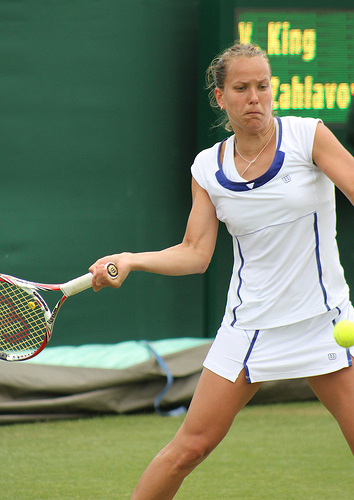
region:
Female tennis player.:
[128, 55, 347, 496]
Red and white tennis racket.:
[3, 216, 88, 368]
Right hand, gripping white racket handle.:
[61, 252, 126, 304]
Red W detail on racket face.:
[1, 284, 28, 354]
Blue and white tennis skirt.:
[213, 316, 352, 384]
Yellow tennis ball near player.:
[334, 316, 352, 356]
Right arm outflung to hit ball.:
[101, 164, 226, 301]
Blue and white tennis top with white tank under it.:
[197, 131, 342, 318]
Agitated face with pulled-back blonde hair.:
[207, 37, 283, 140]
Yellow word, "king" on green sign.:
[267, 22, 323, 72]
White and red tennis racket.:
[0, 258, 119, 358]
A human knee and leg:
[121, 380, 261, 493]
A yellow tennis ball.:
[332, 320, 349, 343]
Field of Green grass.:
[0, 395, 348, 494]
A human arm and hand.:
[87, 185, 213, 286]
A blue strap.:
[136, 332, 182, 421]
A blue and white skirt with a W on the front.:
[202, 291, 349, 381]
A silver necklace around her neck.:
[231, 118, 284, 171]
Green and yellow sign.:
[234, 9, 347, 118]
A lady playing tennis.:
[0, 41, 351, 496]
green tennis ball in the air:
[325, 306, 352, 372]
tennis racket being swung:
[0, 232, 128, 369]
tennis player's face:
[192, 41, 296, 146]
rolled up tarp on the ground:
[0, 329, 230, 424]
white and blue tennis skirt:
[197, 288, 350, 388]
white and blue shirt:
[190, 111, 349, 328]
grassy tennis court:
[7, 399, 346, 495]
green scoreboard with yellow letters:
[214, 9, 339, 118]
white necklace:
[213, 123, 301, 180]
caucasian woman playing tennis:
[2, 53, 340, 494]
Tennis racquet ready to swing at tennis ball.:
[0, 256, 131, 366]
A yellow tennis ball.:
[335, 317, 352, 353]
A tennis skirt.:
[193, 297, 353, 381]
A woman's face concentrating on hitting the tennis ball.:
[202, 43, 282, 134]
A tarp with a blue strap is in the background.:
[0, 338, 232, 428]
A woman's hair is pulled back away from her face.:
[203, 42, 274, 83]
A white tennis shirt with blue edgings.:
[185, 111, 351, 324]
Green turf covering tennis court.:
[5, 399, 344, 498]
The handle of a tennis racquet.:
[51, 265, 122, 297]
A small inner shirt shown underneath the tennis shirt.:
[218, 134, 252, 185]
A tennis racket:
[0, 243, 124, 374]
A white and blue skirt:
[189, 302, 352, 388]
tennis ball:
[334, 308, 353, 351]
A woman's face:
[190, 39, 281, 143]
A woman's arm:
[83, 160, 223, 301]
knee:
[165, 438, 202, 478]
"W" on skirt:
[322, 348, 342, 363]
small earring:
[214, 99, 227, 113]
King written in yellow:
[262, 13, 326, 66]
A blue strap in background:
[115, 325, 195, 422]